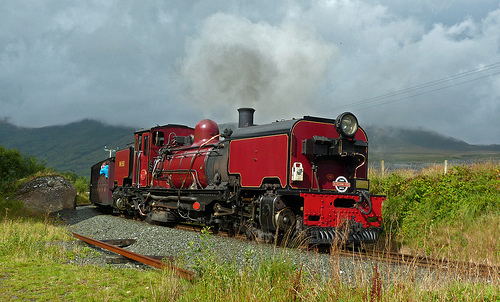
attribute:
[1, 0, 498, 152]
sky — blue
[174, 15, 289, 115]
smoke — gray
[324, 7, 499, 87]
clouds — white 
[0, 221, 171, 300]
grass — tall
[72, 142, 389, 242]
train — red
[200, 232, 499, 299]
weeds — tall 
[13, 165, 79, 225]
boulder — grey, large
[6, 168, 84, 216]
rock — big, gray